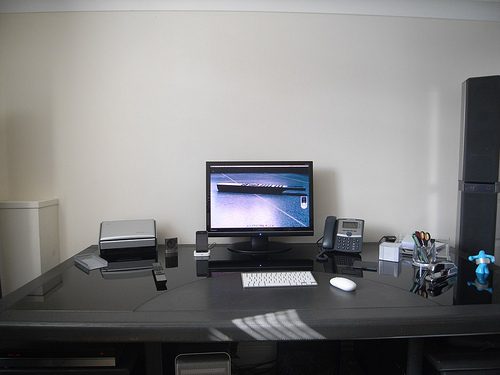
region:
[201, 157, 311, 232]
electronics on black desk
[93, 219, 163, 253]
electronics on black desk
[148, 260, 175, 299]
electronics on black desk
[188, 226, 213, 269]
electronics on black desk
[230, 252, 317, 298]
electronics on black desk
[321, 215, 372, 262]
electronics on black desk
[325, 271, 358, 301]
electronics on black desk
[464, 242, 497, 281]
blue toy on black desk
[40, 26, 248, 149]
white wall by black desk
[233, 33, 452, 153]
white wall by black desk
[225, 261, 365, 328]
the keyboard is white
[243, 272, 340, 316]
the keyboard is white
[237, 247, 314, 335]
the keyboard is white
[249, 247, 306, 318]
the keyboard is white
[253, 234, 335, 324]
the keyboard is white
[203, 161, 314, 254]
computer monitor sitting on top of computer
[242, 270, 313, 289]
very small white keyboard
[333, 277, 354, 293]
white wireless computer mouse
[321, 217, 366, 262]
office type telephone with display screen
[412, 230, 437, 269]
cup filled with pens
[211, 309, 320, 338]
reflection from an unseen window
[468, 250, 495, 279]
little blue man-shaped figurine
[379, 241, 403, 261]
block of tear away note paper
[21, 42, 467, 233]
blank white wall behind dest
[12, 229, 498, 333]
black shiny office desk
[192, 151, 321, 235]
black monitor on desk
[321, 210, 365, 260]
black telephone on desk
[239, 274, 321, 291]
white keyboard on desk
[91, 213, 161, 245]
silver and black printer on desk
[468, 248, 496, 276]
blue toy on desk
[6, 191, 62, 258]
white cabinet in room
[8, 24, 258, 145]
white colored wall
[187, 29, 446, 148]
white colored wall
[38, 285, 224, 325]
black desk with electronics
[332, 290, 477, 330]
black desk with electronics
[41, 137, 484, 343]
a desk in an office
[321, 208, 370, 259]
a handheld phone on a desk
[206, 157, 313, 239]
a computer monitor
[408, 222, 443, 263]
a bunch of pens and a scissor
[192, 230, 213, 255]
a black speaker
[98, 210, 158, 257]
a silvery printer on the desk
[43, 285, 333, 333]
a black shinny desk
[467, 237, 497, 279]
a blue figurine standing on the desk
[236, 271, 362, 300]
a white keyboard and mouse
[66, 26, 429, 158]
a white wall